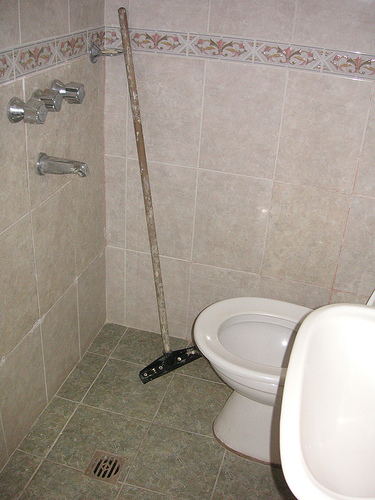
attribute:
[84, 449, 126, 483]
drain — silver, gold, tan colored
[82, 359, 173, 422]
tile — green, greenish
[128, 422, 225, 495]
tile — green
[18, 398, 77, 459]
tile — green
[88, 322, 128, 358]
tile — green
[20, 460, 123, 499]
tile — green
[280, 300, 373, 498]
sink — empty, white, bright white, broad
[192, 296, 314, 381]
toilet seat — clean, elongated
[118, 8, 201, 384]
paint scraper — large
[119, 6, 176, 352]
handle — wooden, stained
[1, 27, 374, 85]
tile lining — pink, green, patterned, brown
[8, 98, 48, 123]
temperature knob — shiny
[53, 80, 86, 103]
temperature knob — shiny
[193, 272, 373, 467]
toilet — white, bright white, porcelain, clean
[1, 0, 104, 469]
wall — beige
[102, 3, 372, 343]
wall — beige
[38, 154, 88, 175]
faucet — silver, metal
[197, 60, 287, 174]
tile — beige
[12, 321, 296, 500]
floor — greenish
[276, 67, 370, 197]
tile — beige